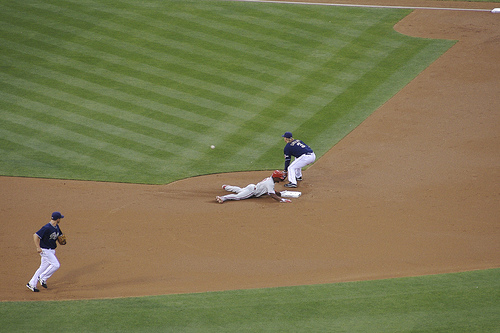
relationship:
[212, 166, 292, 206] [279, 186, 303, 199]
player laying before base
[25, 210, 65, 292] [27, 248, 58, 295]
player in pants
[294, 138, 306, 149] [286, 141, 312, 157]
number on shirt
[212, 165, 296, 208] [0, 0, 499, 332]
baseball player on ground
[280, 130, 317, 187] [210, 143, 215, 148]
player bending over to catch ball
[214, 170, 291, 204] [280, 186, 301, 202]
man laying near base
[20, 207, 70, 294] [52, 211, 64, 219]
man wearing hat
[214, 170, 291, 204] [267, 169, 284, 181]
man wearing helmet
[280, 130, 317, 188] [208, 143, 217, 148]
baseman preparing to catch ball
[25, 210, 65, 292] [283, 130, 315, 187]
player running to back up baseman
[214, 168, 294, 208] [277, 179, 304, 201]
runner touching base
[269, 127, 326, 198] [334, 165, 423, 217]
man on sand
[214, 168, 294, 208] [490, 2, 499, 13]
runner dove for base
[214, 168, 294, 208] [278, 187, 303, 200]
runner dove for base